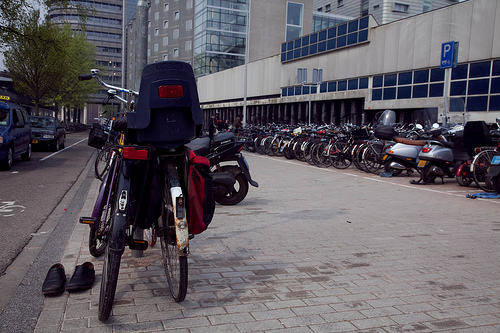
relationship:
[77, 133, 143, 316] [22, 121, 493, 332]
bicycle parked on street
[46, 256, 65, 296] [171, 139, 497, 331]
shoe on street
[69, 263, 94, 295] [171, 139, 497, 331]
shoe on street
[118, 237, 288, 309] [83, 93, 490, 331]
shadow on street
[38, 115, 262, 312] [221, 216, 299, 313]
bicycle casting shadow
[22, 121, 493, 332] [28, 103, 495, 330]
street paved with bricks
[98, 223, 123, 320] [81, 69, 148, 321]
tire of bicycle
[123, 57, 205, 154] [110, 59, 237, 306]
seat of bike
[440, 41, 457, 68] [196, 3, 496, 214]
parking sign on side of building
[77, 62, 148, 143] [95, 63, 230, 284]
handle on back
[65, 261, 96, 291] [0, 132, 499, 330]
shoe on ground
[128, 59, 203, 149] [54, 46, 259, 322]
backpack on bike